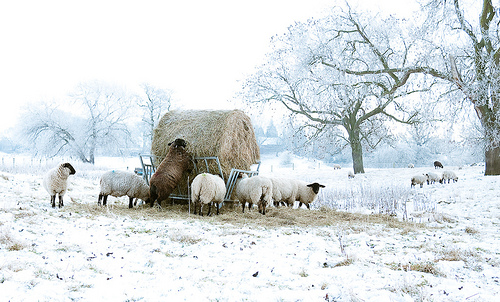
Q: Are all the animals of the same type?
A: Yes, all the animals are sheep.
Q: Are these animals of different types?
A: No, all the animals are sheep.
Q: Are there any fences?
A: No, there are no fences.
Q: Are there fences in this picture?
A: No, there are no fences.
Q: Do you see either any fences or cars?
A: No, there are no fences or cars.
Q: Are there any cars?
A: No, there are no cars.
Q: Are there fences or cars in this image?
A: No, there are no cars or fences.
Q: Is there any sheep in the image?
A: Yes, there is a sheep.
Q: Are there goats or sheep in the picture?
A: Yes, there is a sheep.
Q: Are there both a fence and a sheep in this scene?
A: No, there is a sheep but no fences.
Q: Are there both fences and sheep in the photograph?
A: No, there is a sheep but no fences.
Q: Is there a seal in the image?
A: No, there are no seals.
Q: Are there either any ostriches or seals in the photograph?
A: No, there are no seals or ostriches.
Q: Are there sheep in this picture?
A: Yes, there is a sheep.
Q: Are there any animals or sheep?
A: Yes, there is a sheep.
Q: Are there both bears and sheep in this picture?
A: No, there is a sheep but no bears.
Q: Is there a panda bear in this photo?
A: No, there are no pandas.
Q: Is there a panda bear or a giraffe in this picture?
A: No, there are no pandas or giraffes.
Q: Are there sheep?
A: Yes, there is a sheep.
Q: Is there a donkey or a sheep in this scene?
A: Yes, there is a sheep.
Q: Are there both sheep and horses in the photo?
A: No, there is a sheep but no horses.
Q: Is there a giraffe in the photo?
A: No, there are no giraffes.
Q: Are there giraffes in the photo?
A: No, there are no giraffes.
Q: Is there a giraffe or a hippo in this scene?
A: No, there are no giraffes or hippos.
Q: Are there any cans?
A: No, there are no cans.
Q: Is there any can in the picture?
A: No, there are no cans.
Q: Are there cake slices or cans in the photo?
A: No, there are no cans or cake slices.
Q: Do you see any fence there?
A: No, there are no fences.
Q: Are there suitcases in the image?
A: No, there are no suitcases.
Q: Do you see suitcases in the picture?
A: No, there are no suitcases.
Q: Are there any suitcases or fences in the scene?
A: No, there are no suitcases or fences.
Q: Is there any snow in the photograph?
A: Yes, there is snow.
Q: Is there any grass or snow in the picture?
A: Yes, there is snow.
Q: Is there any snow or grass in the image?
A: Yes, there is snow.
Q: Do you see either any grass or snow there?
A: Yes, there is snow.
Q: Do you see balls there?
A: No, there are no balls.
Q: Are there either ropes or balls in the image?
A: No, there are no balls or ropes.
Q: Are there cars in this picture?
A: No, there are no cars.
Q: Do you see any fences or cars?
A: No, there are no cars or fences.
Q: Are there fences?
A: No, there are no fences.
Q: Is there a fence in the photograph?
A: No, there are no fences.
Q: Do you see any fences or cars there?
A: No, there are no fences or cars.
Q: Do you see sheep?
A: Yes, there is a sheep.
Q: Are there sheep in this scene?
A: Yes, there is a sheep.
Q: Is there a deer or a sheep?
A: Yes, there is a sheep.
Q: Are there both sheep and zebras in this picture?
A: No, there is a sheep but no zebras.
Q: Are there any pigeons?
A: No, there are no pigeons.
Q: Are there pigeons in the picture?
A: No, there are no pigeons.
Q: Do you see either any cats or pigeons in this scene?
A: No, there are no pigeons or cats.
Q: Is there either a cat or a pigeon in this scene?
A: No, there are no pigeons or cats.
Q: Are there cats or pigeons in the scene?
A: No, there are no pigeons or cats.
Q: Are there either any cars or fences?
A: No, there are no cars or fences.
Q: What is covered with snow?
A: The tree is covered with snow.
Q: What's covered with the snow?
A: The tree is covered with snow.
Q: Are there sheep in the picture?
A: Yes, there is a sheep.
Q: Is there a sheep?
A: Yes, there is a sheep.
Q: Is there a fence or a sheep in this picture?
A: Yes, there is a sheep.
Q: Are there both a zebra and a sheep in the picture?
A: No, there is a sheep but no zebras.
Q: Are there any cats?
A: No, there are no cats.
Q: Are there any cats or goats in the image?
A: No, there are no cats or goats.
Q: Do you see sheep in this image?
A: Yes, there is a sheep.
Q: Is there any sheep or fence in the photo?
A: Yes, there is a sheep.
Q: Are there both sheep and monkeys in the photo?
A: No, there is a sheep but no monkeys.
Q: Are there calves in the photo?
A: No, there are no calves.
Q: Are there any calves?
A: No, there are no calves.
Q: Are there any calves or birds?
A: No, there are no calves or birds.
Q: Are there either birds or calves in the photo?
A: No, there are no calves or birds.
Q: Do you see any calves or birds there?
A: No, there are no calves or birds.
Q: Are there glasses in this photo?
A: No, there are no glasses.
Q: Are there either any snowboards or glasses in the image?
A: No, there are no glasses or snowboards.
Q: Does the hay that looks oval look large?
A: Yes, the hay is large.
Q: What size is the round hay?
A: The hay is large.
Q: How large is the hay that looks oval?
A: The hay is large.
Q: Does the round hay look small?
A: No, the hay is large.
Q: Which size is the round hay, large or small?
A: The hay is large.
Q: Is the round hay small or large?
A: The hay is large.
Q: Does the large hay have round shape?
A: Yes, the hay is round.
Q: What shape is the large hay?
A: The hay is round.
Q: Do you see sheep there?
A: Yes, there is a sheep.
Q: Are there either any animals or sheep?
A: Yes, there is a sheep.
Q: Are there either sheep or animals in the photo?
A: Yes, there is a sheep.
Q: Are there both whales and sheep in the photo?
A: No, there is a sheep but no whales.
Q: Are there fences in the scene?
A: No, there are no fences.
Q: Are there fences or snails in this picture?
A: No, there are no fences or snails.